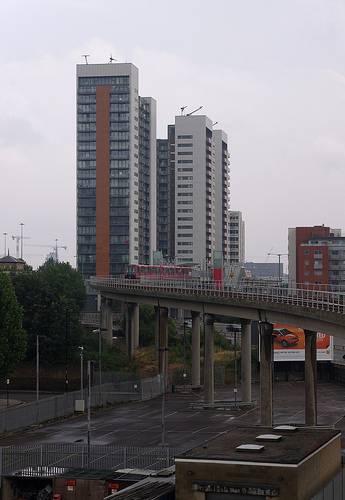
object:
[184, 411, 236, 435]
lot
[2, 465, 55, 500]
tunnel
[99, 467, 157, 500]
trash dumpster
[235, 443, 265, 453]
lid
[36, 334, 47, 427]
street lamp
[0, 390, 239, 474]
parking lot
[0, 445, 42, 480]
fence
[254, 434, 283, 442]
skylight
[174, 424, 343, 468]
roof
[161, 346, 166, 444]
light pole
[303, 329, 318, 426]
support column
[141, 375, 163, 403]
fence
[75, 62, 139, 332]
building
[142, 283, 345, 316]
railway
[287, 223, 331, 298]
buildings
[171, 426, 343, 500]
building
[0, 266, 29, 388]
trees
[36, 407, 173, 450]
land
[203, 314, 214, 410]
pillar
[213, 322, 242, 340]
road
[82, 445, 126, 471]
fence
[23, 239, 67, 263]
crane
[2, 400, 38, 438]
fence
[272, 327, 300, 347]
car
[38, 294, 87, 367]
trees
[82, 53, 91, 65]
antenna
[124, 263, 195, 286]
train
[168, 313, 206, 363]
background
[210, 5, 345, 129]
sky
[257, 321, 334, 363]
billard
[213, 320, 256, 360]
background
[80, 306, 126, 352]
background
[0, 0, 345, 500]
photo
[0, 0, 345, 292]
daytime